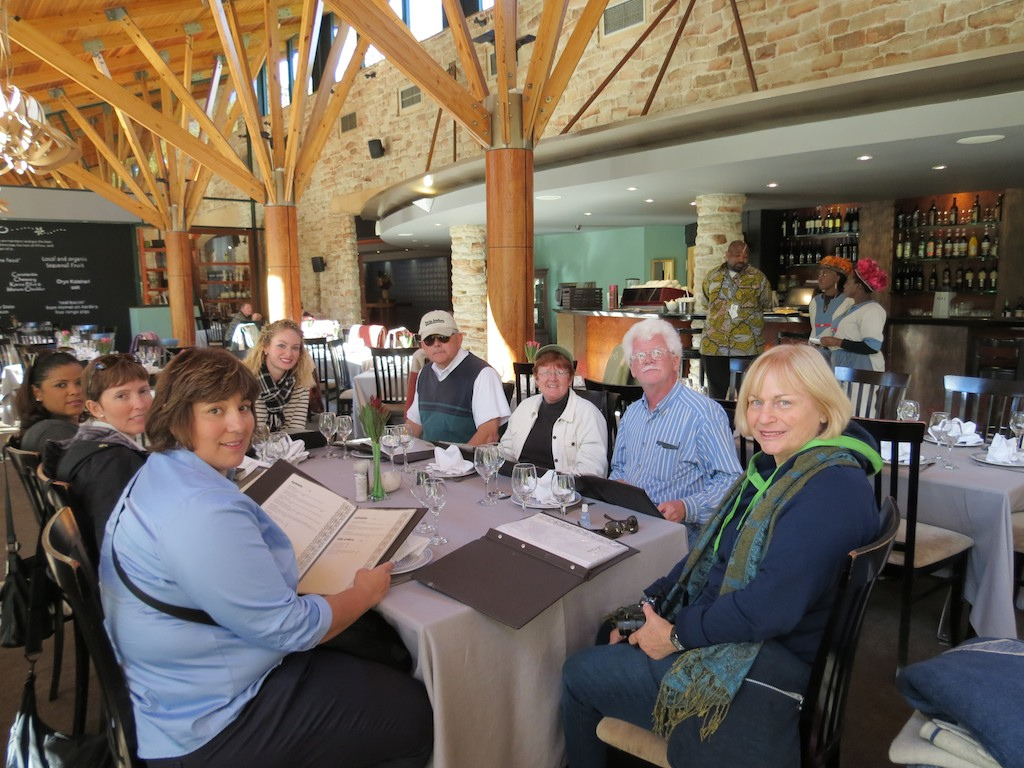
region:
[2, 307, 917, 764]
A group of people sitting around a table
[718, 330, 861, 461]
Woman has short blonde hair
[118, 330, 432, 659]
A woman holding a binder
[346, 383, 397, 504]
A flower in a vase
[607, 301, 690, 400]
White hair on a man's head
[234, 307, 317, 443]
Woman has a scarf around her neck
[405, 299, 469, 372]
Man is wearing a hat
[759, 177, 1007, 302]
Many bottles on shelves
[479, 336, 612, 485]
Lady is wearing a white coat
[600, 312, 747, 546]
The gentleman in the striped shirt is elderly.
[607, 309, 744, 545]
The man's hair is completely white.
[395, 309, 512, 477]
The man is wearing sunglasses.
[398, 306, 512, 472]
The man is wearing a cap.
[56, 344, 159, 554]
The woman has sunglasses on top of her head.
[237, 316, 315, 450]
The woman is wearing a plaid scarf around her neck.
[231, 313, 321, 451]
The woman is seated near the end of the table.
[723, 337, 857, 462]
The woman has short, blonde hair.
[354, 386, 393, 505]
The flower vase is green.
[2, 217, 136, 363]
A blackboard hangs on the far end wall.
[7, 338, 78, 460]
a person is sitting down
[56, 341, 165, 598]
a person is sitting down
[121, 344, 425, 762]
a person is sitting down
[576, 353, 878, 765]
a person is sitting down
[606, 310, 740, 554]
a person is sitting down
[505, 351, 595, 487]
a person is sitting down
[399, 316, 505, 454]
a person is sitting down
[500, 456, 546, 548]
a vessel made for drinking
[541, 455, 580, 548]
a vessel made for drinking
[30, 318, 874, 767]
ten people sitting at table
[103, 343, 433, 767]
women holding binder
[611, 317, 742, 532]
white haired man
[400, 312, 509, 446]
man wearing hat and sunglasses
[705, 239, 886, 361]
three people standing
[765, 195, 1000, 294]
shelves holding bottles of wine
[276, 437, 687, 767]
table with light purple cloth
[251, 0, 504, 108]
window showing light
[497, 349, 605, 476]
woman wearing white jacket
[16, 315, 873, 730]
people sitting at a table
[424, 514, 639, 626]
a menu on the table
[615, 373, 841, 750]
a lady with a scarf on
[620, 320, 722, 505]
a man in a blue shirt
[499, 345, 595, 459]
a lady in a white jacket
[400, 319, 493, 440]
a man with a white cap on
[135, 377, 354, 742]
a woman with a blue shirt on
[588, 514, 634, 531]
sunglasses on the table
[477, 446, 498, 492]
a glass on the table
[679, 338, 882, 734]
Woman with blond hair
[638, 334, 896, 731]
Woman sitting at table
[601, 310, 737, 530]
Man with white hair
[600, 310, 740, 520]
Man in blue shirt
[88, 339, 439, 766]
woman with blue shirt reading a menu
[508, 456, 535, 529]
wine glass on table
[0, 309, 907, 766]
people sitting around table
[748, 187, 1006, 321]
bottles lining the wall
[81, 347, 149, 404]
sunglasses on woman's head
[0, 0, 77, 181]
chandelier hanging from ceiling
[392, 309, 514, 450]
man wearing cap and vest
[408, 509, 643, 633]
menu resting on table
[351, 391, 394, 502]
rose in vase on table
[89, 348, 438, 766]
person sitting in the restaurant